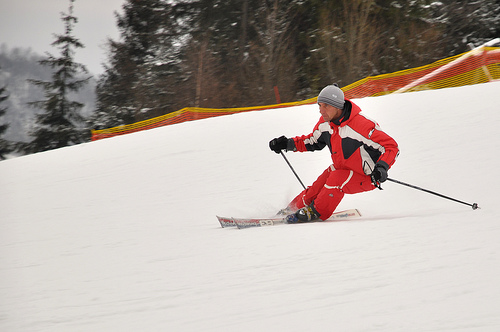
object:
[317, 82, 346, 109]
hat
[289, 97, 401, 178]
jacket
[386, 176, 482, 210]
skis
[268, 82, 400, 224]
man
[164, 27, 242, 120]
trees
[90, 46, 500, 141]
fence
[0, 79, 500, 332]
snow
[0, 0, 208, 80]
sky